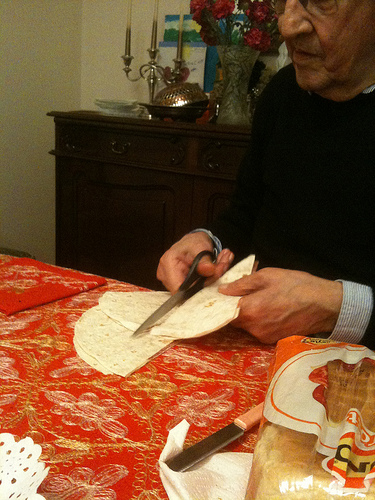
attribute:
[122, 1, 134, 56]
candlestick — silver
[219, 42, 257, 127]
vase — clear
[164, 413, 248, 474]
blade — silver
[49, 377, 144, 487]
napkin — red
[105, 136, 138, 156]
handle — metal 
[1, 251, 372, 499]
tablecloth — red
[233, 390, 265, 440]
handle — brown, wooden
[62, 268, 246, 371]
tortillas — white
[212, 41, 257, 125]
vase — clear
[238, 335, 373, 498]
bread — loaf 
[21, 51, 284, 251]
furniture — wooden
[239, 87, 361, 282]
shirt — striped 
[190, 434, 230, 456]
knife — small , wooden 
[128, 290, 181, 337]
blade — silver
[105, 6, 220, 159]
candleabra — silver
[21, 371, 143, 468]
design — gold, red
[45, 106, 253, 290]
furniture — dark brown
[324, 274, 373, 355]
cuff — striped 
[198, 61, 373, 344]
sweater — black 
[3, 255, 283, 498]
stitching — gold , white 